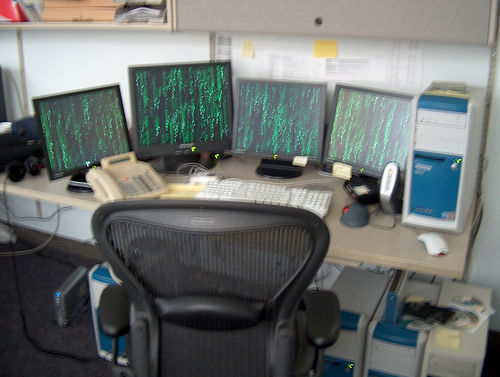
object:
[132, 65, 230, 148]
monitor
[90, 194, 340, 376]
chair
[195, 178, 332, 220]
keyboard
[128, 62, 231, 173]
computer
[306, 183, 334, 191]
key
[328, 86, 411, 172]
monitor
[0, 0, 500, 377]
office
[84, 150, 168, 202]
phone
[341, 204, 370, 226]
mouse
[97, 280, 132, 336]
armrest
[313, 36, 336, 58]
paper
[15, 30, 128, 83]
wall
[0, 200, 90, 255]
wires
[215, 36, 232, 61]
white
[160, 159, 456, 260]
surface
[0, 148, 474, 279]
desk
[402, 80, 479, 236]
cpu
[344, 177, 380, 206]
modem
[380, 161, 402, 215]
light